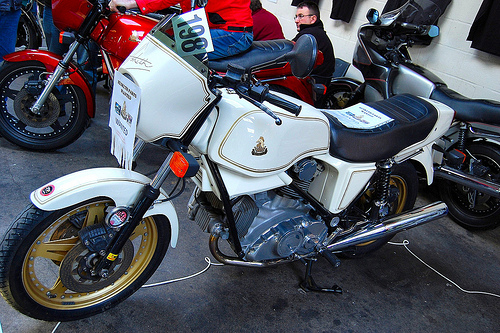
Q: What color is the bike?
A: White.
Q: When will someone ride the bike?
A: Once they're done taking pictures.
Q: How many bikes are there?
A: Two.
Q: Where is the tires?
A: On the bike.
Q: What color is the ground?
A: Gray.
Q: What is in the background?
A: A person.